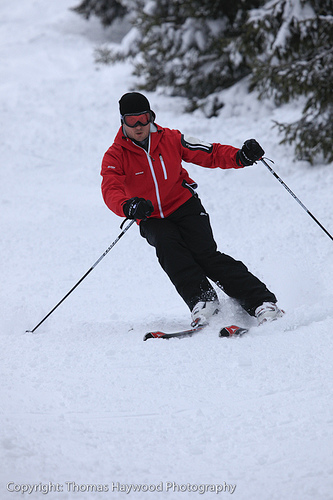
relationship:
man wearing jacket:
[102, 92, 279, 328] [102, 129, 241, 222]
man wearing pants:
[102, 92, 279, 328] [138, 192, 277, 316]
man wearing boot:
[102, 92, 279, 328] [184, 289, 219, 329]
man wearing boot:
[102, 92, 279, 328] [249, 291, 279, 324]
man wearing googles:
[102, 92, 279, 328] [121, 110, 154, 130]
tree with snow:
[246, 0, 333, 165] [242, 1, 318, 52]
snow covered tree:
[74, 1, 332, 167] [73, 0, 258, 89]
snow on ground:
[286, 264, 333, 456] [4, 348, 331, 474]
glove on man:
[121, 194, 155, 224] [102, 92, 279, 328]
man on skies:
[102, 92, 279, 328] [145, 324, 262, 341]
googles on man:
[121, 110, 154, 130] [102, 92, 279, 328]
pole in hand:
[259, 156, 332, 239] [237, 135, 266, 167]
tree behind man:
[73, 0, 258, 89] [102, 92, 279, 328]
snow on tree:
[74, 1, 332, 167] [73, 0, 258, 89]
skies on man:
[145, 324, 262, 341] [102, 92, 279, 328]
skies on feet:
[145, 324, 262, 341] [191, 300, 280, 327]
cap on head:
[120, 94, 152, 117] [120, 94, 154, 143]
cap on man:
[120, 94, 152, 117] [102, 92, 279, 328]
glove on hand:
[237, 135, 265, 169] [237, 135, 266, 167]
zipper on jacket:
[144, 149, 163, 220] [102, 129, 241, 222]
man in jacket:
[102, 92, 279, 328] [102, 129, 241, 222]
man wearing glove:
[102, 92, 279, 328] [121, 194, 155, 224]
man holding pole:
[102, 92, 279, 328] [259, 156, 332, 239]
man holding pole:
[102, 92, 279, 328] [35, 216, 137, 338]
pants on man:
[138, 192, 277, 316] [102, 92, 279, 328]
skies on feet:
[145, 324, 262, 341] [186, 301, 277, 326]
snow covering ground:
[286, 264, 333, 456] [4, 348, 331, 474]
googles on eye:
[121, 110, 154, 130] [127, 116, 134, 125]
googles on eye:
[121, 110, 154, 130] [140, 115, 146, 123]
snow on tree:
[242, 1, 318, 52] [246, 0, 333, 165]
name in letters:
[65, 479, 163, 498] [6, 480, 236, 500]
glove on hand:
[121, 194, 155, 224] [125, 197, 153, 222]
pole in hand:
[35, 216, 137, 338] [125, 197, 153, 222]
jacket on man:
[102, 129, 241, 222] [102, 92, 279, 328]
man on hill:
[102, 92, 279, 328] [1, 2, 103, 339]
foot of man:
[191, 297, 221, 330] [102, 92, 279, 328]